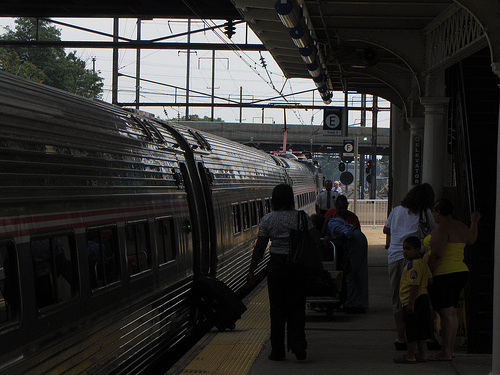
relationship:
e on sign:
[329, 115, 337, 126] [326, 110, 346, 137]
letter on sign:
[341, 142, 357, 153] [340, 136, 355, 163]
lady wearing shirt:
[423, 197, 482, 360] [425, 233, 470, 275]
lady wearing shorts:
[425, 191, 478, 343] [394, 289, 449, 349]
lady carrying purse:
[252, 170, 329, 360] [297, 205, 320, 274]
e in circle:
[329, 115, 335, 125] [326, 114, 340, 128]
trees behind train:
[4, 15, 114, 105] [11, 45, 398, 346]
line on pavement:
[213, 271, 261, 359] [322, 214, 437, 361]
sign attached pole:
[323, 106, 345, 136] [268, 1, 343, 111]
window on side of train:
[19, 237, 81, 310] [3, 65, 325, 374]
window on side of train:
[79, 226, 121, 288] [3, 65, 325, 374]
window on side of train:
[119, 221, 152, 280] [3, 65, 325, 374]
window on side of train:
[148, 216, 175, 268] [3, 65, 325, 374]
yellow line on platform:
[199, 294, 273, 369] [168, 222, 498, 373]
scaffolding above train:
[110, 19, 387, 113] [11, 133, 243, 316]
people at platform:
[235, 176, 495, 369] [161, 201, 499, 373]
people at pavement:
[255, 171, 451, 355] [165, 224, 463, 373]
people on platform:
[245, 178, 480, 362] [303, 191, 409, 248]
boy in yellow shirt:
[390, 234, 438, 366] [393, 258, 433, 303]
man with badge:
[313, 177, 356, 239] [329, 192, 336, 200]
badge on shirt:
[329, 192, 336, 200] [251, 209, 311, 269]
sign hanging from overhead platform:
[309, 103, 363, 139] [233, 217, 450, 373]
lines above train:
[0, 12, 360, 123] [3, 65, 325, 374]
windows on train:
[43, 167, 218, 336] [3, 65, 325, 374]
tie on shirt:
[324, 190, 331, 210] [313, 189, 341, 210]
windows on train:
[8, 181, 283, 317] [3, 65, 325, 374]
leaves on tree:
[3, 19, 104, 99] [2, 19, 109, 95]